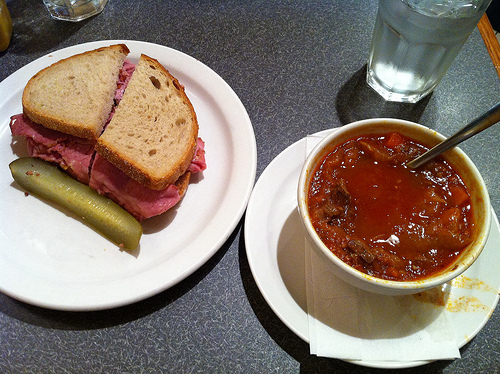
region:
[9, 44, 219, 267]
a beef sandwich on a white plate with a pickle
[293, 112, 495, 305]
white bowl full of chili with a spoon in it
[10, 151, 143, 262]
green dill pickle next to the sandwich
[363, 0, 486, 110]
clear glass of ice water on the table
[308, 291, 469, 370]
white napkin on the plate under the bowl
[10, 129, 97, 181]
piled roast beef on a sandwich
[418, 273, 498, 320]
spilled chili on the plate it's served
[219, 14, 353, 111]
grey speckled table top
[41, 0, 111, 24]
bottom of a clear glass of water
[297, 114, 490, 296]
bowl sits on plate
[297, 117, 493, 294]
bowl has spoon in it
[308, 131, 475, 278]
chili has spoon in it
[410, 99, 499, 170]
spoon is in chili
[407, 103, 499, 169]
spoon is in bowl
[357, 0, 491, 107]
glass has water in it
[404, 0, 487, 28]
ice is in glass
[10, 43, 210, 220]
sandwich is cut in half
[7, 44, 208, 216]
sandwich sits on plate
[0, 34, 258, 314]
plate has sandwich on it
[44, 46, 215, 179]
a pieces of bread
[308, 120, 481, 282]
a tasty food in cup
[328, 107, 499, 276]
a red tasty food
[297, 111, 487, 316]
a red juice in cup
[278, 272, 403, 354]
shadow of the cup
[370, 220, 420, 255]
light on the juice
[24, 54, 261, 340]
a plate with bread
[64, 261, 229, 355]
white curve of the plate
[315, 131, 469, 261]
this is meat stew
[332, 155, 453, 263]
the soup is red in color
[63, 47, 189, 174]
this is a sandwich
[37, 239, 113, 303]
this is a plate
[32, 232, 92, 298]
the plate is white in color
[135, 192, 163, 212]
this is the sausage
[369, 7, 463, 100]
this is a glass of water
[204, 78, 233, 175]
this is a plate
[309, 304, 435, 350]
this is a serviate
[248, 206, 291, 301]
this is a plate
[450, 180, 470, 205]
this is a carrot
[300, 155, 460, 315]
this is a food container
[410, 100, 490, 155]
this is a spoon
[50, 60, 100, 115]
this is a piece of bread